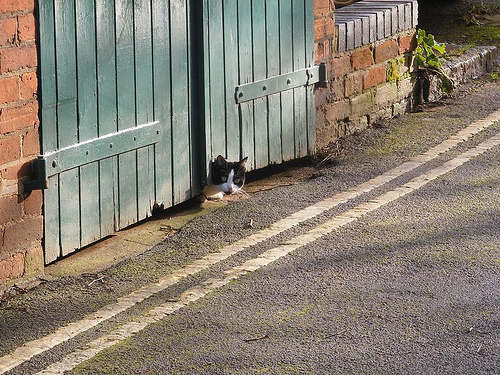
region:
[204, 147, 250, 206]
Head of a black and white cat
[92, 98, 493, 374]
White lines on the ground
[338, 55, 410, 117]
Bricks on a building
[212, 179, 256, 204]
Whiskers on the cat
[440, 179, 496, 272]
Shadows on the ground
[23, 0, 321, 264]
Blue wooden doors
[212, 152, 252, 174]
Two ears on a cat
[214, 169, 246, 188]
Two yellow eyes on a cat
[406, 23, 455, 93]
Green leaves on the building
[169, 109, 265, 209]
Cat sticking head out under the doors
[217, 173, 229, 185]
The Cat's Right Eye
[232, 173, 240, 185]
The Cat's Left Eye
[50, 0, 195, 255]
A wooden cyan door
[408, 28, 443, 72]
Green Leaves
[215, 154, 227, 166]
The Right Ear of the Cat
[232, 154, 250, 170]
The Left Ear of the Cat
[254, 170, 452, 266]
Two Yellow Street Lines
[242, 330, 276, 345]
A small wooden twig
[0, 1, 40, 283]
A long wooden wall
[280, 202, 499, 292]
The Shadow of an object to the right of the picture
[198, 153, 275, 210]
black and white cat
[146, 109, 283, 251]
cat head under door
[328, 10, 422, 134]
brick wall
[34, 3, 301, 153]
two green doors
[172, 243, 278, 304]
two parallel white lines on the ground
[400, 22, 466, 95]
green plant near bricks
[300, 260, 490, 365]
grey concreted ground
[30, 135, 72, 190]
hinge for door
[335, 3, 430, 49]
grey colored bricks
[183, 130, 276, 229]
black and white cat stuck under door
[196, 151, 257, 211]
Head of cat sticking out of a door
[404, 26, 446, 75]
Green plant growing from step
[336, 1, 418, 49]
Grey bricks on top of wall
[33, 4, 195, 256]
Green slatted door on left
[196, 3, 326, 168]
Green slatted door on right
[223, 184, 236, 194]
Nose of the cat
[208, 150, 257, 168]
Ears of the cat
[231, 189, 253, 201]
Whiskers of the cat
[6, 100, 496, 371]
White lines painted on the ground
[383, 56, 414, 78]
Green moss growing on a brick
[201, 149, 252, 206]
Cat in black and white fur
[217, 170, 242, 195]
Cat looks suprised with eyes wide open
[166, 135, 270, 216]
Cat's head sticking out of wooden door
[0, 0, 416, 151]
Brick building with green wooden doors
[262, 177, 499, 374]
Ground paved with asphalt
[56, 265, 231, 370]
Double white lines next to building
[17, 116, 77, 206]
Hinge of doors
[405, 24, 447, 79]
Small green plant at edge of building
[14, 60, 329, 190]
Two wooden doors not well aligned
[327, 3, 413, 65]
Grey bricks